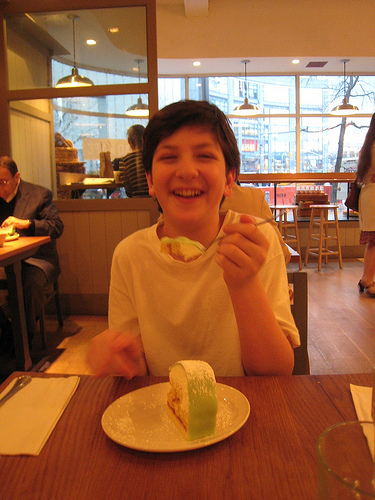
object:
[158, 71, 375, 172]
bay window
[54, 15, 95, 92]
light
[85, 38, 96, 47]
light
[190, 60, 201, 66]
light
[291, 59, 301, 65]
light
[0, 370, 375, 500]
table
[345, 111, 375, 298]
woman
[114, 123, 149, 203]
woman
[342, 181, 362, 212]
purse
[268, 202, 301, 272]
stool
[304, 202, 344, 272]
stool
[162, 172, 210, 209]
smile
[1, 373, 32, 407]
utensil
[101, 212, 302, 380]
shirt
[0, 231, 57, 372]
restaurant table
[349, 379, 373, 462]
napkin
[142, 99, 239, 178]
hair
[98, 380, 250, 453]
plate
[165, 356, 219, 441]
cake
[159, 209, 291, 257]
fork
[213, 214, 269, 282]
hand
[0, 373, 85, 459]
napkin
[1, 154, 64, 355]
man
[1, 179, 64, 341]
suit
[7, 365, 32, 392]
handle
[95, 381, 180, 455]
sugar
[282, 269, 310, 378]
chair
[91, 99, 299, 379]
boy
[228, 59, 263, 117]
lights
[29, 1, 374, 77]
ceiling